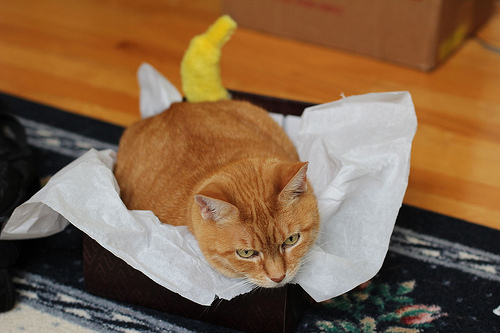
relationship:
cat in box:
[126, 100, 304, 251] [80, 229, 313, 332]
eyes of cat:
[226, 236, 311, 261] [126, 100, 304, 251]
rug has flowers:
[1, 120, 499, 332] [325, 287, 386, 332]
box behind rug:
[226, 3, 496, 57] [1, 120, 499, 332]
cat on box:
[126, 100, 304, 251] [88, 251, 286, 331]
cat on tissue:
[126, 100, 304, 251] [285, 90, 421, 205]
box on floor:
[226, 3, 496, 57] [26, 7, 494, 179]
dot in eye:
[243, 246, 250, 258] [236, 246, 268, 266]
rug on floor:
[1, 120, 499, 332] [26, 7, 494, 179]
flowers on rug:
[325, 287, 386, 332] [1, 120, 499, 332]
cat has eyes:
[126, 100, 304, 251] [226, 236, 311, 261]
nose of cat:
[267, 273, 289, 285] [126, 100, 304, 251]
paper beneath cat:
[303, 79, 408, 210] [126, 100, 304, 251]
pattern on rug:
[335, 284, 477, 332] [1, 120, 499, 332]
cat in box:
[126, 100, 304, 251] [88, 251, 286, 331]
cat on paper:
[126, 100, 304, 251] [303, 79, 408, 210]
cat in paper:
[126, 100, 304, 251] [303, 79, 408, 210]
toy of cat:
[174, 18, 244, 103] [126, 100, 304, 251]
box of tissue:
[88, 251, 286, 331] [285, 90, 421, 205]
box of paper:
[88, 251, 286, 331] [303, 79, 408, 210]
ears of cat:
[190, 145, 306, 211] [126, 100, 304, 251]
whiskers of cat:
[288, 251, 349, 293] [126, 100, 304, 251]